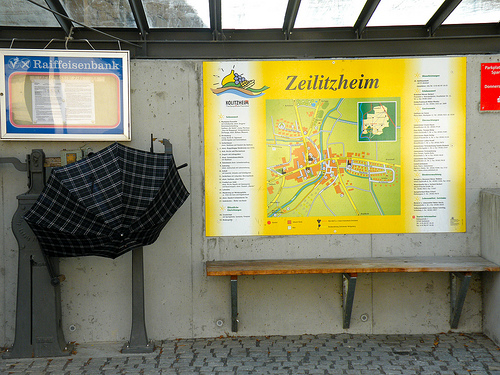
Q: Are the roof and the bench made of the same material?
A: No, the roof is made of glass and the bench is made of wood.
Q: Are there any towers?
A: No, there are no towers.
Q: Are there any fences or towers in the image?
A: No, there are no towers or fences.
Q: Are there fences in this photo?
A: No, there are no fences.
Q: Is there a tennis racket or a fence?
A: No, there are no fences or rackets.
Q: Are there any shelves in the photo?
A: No, there are no shelves.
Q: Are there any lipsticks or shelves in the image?
A: No, there are no shelves or lipsticks.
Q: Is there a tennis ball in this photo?
A: No, there are no tennis balls.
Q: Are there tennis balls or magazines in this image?
A: No, there are no tennis balls or magazines.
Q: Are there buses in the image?
A: No, there are no buses.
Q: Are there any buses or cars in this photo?
A: No, there are no buses or cars.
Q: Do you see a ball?
A: No, there are no balls.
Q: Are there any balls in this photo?
A: No, there are no balls.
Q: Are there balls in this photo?
A: No, there are no balls.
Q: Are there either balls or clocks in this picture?
A: No, there are no balls or clocks.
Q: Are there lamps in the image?
A: No, there are no lamps.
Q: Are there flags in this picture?
A: No, there are no flags.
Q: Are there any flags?
A: No, there are no flags.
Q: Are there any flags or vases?
A: No, there are no flags or vases.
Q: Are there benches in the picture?
A: Yes, there is a bench.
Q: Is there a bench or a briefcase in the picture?
A: Yes, there is a bench.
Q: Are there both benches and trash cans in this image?
A: No, there is a bench but no trash cans.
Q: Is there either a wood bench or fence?
A: Yes, there is a wood bench.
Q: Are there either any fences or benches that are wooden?
A: Yes, the bench is wooden.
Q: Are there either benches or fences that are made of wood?
A: Yes, the bench is made of wood.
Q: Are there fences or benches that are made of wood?
A: Yes, the bench is made of wood.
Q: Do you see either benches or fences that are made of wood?
A: Yes, the bench is made of wood.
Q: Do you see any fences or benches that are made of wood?
A: Yes, the bench is made of wood.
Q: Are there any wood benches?
A: Yes, there is a bench that is made of wood.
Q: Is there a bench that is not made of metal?
A: Yes, there is a bench that is made of wood.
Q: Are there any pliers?
A: No, there are no pliers.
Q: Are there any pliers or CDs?
A: No, there are no pliers or cds.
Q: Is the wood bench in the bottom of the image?
A: Yes, the bench is in the bottom of the image.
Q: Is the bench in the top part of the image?
A: No, the bench is in the bottom of the image.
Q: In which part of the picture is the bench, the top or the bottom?
A: The bench is in the bottom of the image.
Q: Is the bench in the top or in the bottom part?
A: The bench is in the bottom of the image.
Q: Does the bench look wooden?
A: Yes, the bench is wooden.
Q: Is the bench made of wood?
A: Yes, the bench is made of wood.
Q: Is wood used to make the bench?
A: Yes, the bench is made of wood.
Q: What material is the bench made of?
A: The bench is made of wood.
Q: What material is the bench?
A: The bench is made of wood.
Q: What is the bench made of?
A: The bench is made of wood.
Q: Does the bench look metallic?
A: No, the bench is wooden.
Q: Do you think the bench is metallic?
A: No, the bench is wooden.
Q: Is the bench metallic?
A: No, the bench is wooden.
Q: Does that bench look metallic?
A: No, the bench is wooden.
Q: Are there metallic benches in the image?
A: No, there is a bench but it is wooden.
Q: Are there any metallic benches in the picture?
A: No, there is a bench but it is wooden.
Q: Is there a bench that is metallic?
A: No, there is a bench but it is wooden.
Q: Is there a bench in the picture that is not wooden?
A: No, there is a bench but it is wooden.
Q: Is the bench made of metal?
A: No, the bench is made of wood.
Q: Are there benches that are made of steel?
A: No, there is a bench but it is made of wood.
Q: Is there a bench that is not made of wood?
A: No, there is a bench but it is made of wood.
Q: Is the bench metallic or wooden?
A: The bench is wooden.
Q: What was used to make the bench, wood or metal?
A: The bench is made of wood.